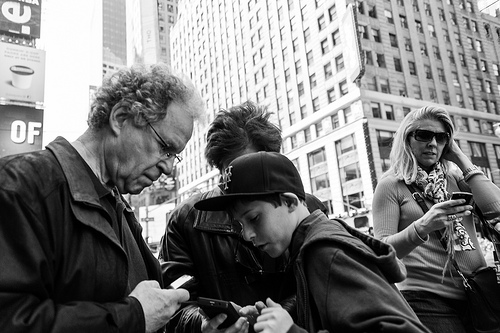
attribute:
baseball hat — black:
[193, 149, 307, 212]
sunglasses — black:
[410, 127, 451, 146]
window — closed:
[333, 130, 357, 156]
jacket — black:
[2, 136, 166, 330]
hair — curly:
[86, 60, 204, 129]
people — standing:
[2, 62, 498, 332]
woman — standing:
[370, 105, 499, 333]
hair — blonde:
[380, 105, 457, 190]